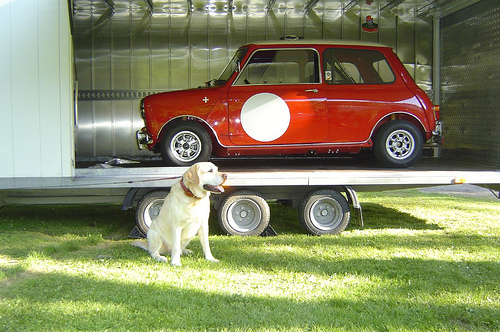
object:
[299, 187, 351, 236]
axel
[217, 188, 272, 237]
axel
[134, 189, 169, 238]
axel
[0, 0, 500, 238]
truck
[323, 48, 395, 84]
window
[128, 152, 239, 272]
lab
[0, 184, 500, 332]
field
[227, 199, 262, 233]
hubcap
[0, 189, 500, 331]
grass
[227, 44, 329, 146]
door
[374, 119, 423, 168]
tire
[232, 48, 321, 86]
side window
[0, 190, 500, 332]
ground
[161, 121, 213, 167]
tire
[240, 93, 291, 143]
circle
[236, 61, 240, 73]
mirror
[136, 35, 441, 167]
red cr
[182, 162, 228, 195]
head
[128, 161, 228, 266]
dog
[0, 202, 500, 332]
shadow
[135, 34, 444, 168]
car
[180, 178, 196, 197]
collar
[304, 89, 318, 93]
handle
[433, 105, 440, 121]
light